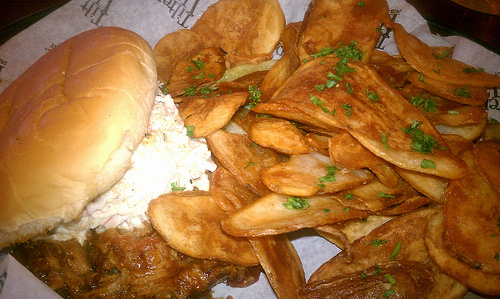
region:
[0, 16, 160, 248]
a brown hamburg bun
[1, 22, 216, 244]
brown hamburg bun look like white chicken under it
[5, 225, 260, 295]
brown hamburg bun look like brown chicken under it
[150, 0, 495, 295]
it look like potatoes slices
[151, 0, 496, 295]
lots of green season on it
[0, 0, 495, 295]
sitting on a wrap paper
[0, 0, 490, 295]
wrap paper has writing on it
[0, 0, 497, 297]
wrap paper is white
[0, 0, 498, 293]
look like at a Chinese restaurant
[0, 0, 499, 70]
look dark in the back ground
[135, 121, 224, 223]
This is cheese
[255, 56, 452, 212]
This is a potato's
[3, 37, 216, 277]
This is a bread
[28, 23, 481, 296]
This is at restaurant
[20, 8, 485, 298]
this is someones food.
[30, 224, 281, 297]
This is some bacon.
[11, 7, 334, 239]
This food has plastic underneath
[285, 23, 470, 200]
The green stuff is parsley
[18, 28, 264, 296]
This is a hamburger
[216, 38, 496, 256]
These are fries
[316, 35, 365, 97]
a pile of chopped herbs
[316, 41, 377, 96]
small pieces of herb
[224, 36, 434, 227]
wide slices of potato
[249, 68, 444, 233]
a pile of potato chips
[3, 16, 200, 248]
a plain burger bun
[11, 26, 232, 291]
a very large sandwich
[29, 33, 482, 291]
a cheap unhealthy lunch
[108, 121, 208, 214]
a pile of food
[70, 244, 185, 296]
some melted cheese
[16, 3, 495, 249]
some food sitting on paper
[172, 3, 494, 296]
a lot of french fries on the plate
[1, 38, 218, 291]
a hamburger next to the fries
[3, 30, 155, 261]
the bun of the hamburger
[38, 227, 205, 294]
the meat of the burger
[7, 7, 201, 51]
the paper under the food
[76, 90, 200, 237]
the cheese under the bun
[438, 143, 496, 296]
a large french fry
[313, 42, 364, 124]
some green pieces of food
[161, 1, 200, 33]
the writing on the paper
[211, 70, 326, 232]
some more french fries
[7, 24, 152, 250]
white and tan hamburger bun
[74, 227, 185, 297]
brown and tan meat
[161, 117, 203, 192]
white topping on hamburger bun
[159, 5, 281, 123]
brown colored french fries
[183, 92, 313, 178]
brown colored french fries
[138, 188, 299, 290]
brown colored french fries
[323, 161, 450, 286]
brown colored french fries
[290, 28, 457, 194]
brown colored french fries with green topping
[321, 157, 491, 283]
brown colored french fries with green topping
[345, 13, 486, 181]
brown colored french fries with green topping